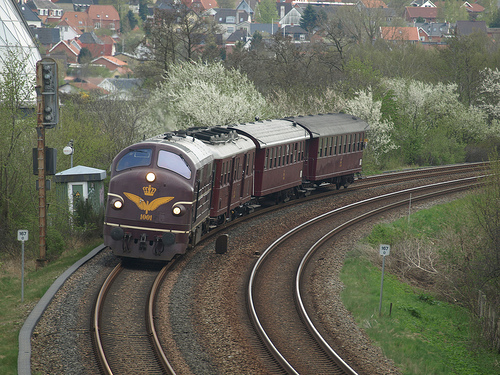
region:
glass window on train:
[359, 131, 364, 151]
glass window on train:
[354, 132, 361, 153]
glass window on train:
[116, 148, 155, 167]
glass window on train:
[158, 147, 189, 182]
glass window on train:
[220, 160, 225, 187]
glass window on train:
[263, 146, 268, 170]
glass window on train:
[267, 148, 274, 168]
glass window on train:
[273, 144, 278, 166]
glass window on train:
[285, 140, 290, 164]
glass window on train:
[297, 140, 302, 162]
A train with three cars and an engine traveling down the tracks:
[100, 107, 371, 264]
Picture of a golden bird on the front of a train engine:
[121, 190, 176, 215]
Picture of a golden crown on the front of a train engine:
[141, 181, 155, 198]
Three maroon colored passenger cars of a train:
[175, 109, 372, 225]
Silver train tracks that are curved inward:
[242, 173, 498, 374]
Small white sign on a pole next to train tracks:
[12, 225, 31, 300]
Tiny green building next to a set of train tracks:
[51, 160, 108, 237]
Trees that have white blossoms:
[125, 53, 497, 175]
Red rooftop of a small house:
[377, 23, 420, 42]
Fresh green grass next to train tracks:
[335, 184, 497, 373]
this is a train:
[64, 94, 396, 245]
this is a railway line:
[236, 248, 317, 323]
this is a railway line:
[266, 213, 329, 275]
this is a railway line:
[326, 185, 403, 220]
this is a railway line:
[101, 243, 166, 338]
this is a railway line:
[86, 315, 157, 369]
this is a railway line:
[176, 257, 253, 329]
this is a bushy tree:
[389, 70, 471, 170]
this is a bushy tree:
[339, 85, 398, 171]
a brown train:
[98, 112, 380, 265]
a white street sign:
[378, 243, 390, 318]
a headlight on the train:
[147, 173, 157, 183]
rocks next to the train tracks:
[318, 267, 373, 334]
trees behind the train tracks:
[346, 71, 493, 117]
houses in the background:
[48, 14, 498, 66]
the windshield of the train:
[121, 148, 186, 171]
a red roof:
[386, 23, 428, 41]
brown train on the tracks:
[69, 83, 389, 251]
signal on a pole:
[31, 56, 58, 138]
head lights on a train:
[110, 194, 182, 217]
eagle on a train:
[123, 178, 177, 223]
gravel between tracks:
[180, 277, 218, 359]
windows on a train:
[218, 153, 253, 185]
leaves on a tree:
[383, 79, 485, 149]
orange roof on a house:
[84, 55, 131, 67]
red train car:
[207, 136, 310, 194]